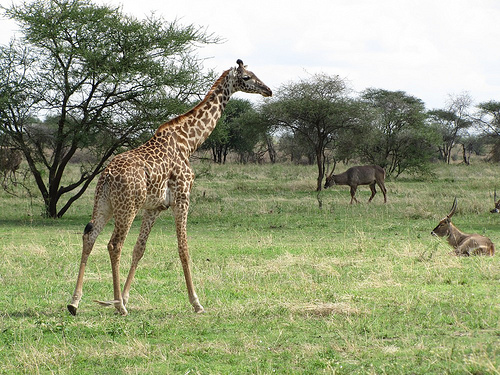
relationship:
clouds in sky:
[312, 2, 495, 68] [250, 0, 390, 67]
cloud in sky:
[82, 0, 496, 75] [0, 3, 495, 136]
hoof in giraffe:
[66, 304, 78, 315] [66, 57, 274, 314]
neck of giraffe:
[200, 76, 234, 122] [66, 57, 274, 314]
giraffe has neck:
[60, 54, 275, 357] [160, 96, 249, 168]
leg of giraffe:
[175, 208, 202, 312] [78, 65, 268, 313]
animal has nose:
[430, 204, 495, 257] [430, 232, 435, 238]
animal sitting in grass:
[397, 170, 487, 277] [37, 144, 494, 374]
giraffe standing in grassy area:
[87, 63, 256, 297] [243, 241, 427, 341]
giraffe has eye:
[66, 57, 274, 314] [242, 72, 252, 82]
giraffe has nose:
[191, 48, 272, 268] [265, 89, 275, 96]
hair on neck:
[161, 86, 210, 123] [91, 46, 269, 246]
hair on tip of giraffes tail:
[85, 216, 92, 235] [79, 179, 106, 244]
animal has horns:
[49, 36, 292, 349] [447, 193, 461, 218]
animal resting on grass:
[429, 200, 493, 260] [262, 223, 463, 350]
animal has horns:
[65, 15, 310, 369] [445, 193, 461, 224]